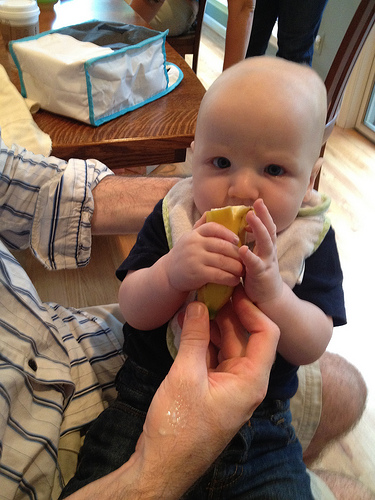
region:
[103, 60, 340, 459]
this is a boy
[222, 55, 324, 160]
the boy is bald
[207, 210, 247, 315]
this is a banana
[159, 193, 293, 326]
the boy is holding the banana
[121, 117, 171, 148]
this is the table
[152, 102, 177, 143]
the table is wooden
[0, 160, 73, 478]
this is an adult man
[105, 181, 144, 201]
the arm is hairy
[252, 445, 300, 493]
the trouser is blue in color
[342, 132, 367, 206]
this is the floor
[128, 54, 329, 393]
a baby eating a banana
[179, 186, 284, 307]
baby holding a half banana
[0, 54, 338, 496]
man holding a baby on his lap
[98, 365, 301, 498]
baby wearing blue jeans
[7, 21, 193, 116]
a bag on a table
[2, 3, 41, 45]
a plastic cup of coffe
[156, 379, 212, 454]
moisture on a man's hand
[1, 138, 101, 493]
blue and white stripe shirt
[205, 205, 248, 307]
a half banana in a baby's hand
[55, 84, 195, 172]
a wooden table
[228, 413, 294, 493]
the short is blue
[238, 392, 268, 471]
the short is blue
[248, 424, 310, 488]
the short is blue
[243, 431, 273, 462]
the short is blue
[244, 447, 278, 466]
the short is blue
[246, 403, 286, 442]
the short is blue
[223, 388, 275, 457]
the short is blue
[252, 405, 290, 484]
the short is blue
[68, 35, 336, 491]
baby wearing a bib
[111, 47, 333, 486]
baby eating a banana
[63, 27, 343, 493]
baby wearing a blue shirt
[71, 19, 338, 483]
baby wearing dark jean pants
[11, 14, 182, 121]
blue and white diaper bag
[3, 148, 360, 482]
man holding a baby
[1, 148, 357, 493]
man wearing stripped shirt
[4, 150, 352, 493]
man with hairy legs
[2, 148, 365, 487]
man wearing tan shorts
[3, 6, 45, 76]
empty baby bottle on the table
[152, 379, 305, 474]
the hand is wet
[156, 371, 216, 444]
the hand is wet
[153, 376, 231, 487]
the hand is wet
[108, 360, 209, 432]
the hand is wet